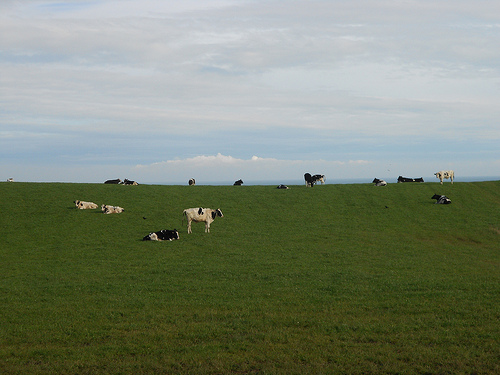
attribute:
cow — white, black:
[142, 225, 186, 246]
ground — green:
[371, 164, 392, 190]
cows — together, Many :
[181, 205, 226, 232]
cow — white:
[179, 205, 224, 235]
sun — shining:
[16, 9, 494, 183]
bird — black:
[128, 202, 159, 227]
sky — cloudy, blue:
[1, 2, 498, 184]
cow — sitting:
[141, 227, 180, 243]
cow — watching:
[174, 201, 229, 231]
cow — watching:
[140, 226, 183, 243]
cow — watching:
[98, 200, 126, 215]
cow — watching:
[431, 187, 452, 206]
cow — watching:
[429, 165, 461, 190]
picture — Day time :
[1, 3, 496, 373]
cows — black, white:
[141, 193, 262, 241]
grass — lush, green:
[0, 182, 500, 373]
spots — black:
[193, 207, 207, 215]